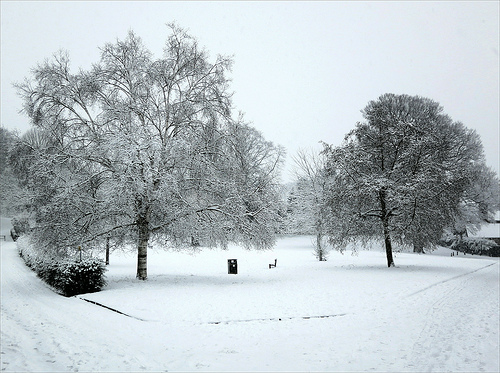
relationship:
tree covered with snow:
[304, 93, 500, 267] [14, 40, 493, 360]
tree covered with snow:
[280, 176, 324, 234] [14, 40, 493, 360]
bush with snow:
[16, 240, 109, 297] [23, 240, 62, 270]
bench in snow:
[269, 259, 277, 269] [2, 233, 483, 371]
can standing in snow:
[228, 254, 248, 283] [14, 40, 493, 360]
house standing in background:
[426, 193, 493, 270] [2, 127, 484, 257]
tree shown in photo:
[303, 90, 489, 260] [2, 2, 484, 371]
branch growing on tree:
[357, 200, 425, 271] [316, 91, 485, 266]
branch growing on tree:
[57, 220, 137, 246] [25, 35, 282, 325]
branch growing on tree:
[150, 205, 262, 231] [25, 35, 282, 325]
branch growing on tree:
[68, 208, 95, 222] [25, 35, 282, 325]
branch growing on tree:
[124, 103, 164, 142] [25, 35, 282, 325]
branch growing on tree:
[28, 90, 93, 130] [25, 35, 282, 325]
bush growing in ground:
[7, 226, 104, 304] [252, 260, 364, 316]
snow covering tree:
[16, 27, 281, 242] [0, 20, 289, 283]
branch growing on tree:
[146, 205, 265, 234] [19, 16, 290, 298]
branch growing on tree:
[57, 220, 137, 246] [19, 16, 290, 298]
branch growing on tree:
[28, 90, 93, 130] [19, 16, 290, 298]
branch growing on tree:
[64, 90, 84, 107] [19, 16, 290, 298]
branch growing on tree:
[132, 107, 163, 141] [19, 16, 290, 298]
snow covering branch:
[7, 20, 287, 255] [146, 205, 265, 234]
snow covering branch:
[7, 20, 287, 255] [57, 220, 137, 246]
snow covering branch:
[7, 20, 287, 255] [28, 90, 93, 130]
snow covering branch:
[7, 20, 287, 255] [64, 90, 84, 107]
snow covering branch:
[7, 20, 287, 255] [132, 107, 163, 141]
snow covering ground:
[2, 233, 483, 371] [24, 291, 230, 371]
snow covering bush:
[34, 256, 105, 297] [16, 240, 109, 297]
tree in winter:
[304, 93, 500, 267] [4, 3, 498, 368]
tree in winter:
[280, 176, 324, 234] [4, 3, 498, 368]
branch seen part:
[190, 204, 205, 219] [192, 210, 199, 219]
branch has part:
[383, 205, 400, 224] [397, 214, 398, 217]